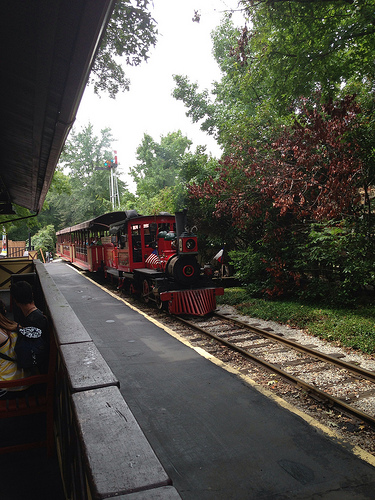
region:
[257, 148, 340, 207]
brown leaves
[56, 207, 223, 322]
a red and black train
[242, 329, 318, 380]
railroad tracks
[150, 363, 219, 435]
black pavement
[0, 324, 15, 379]
a yellow and white shirt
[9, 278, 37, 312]
a person with black hair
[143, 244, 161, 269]
a red, white and blue flag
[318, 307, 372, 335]
green grass with brown leaves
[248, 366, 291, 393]
green and brown leaves on a railroad track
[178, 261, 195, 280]
a red circle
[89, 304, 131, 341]
small spot on platform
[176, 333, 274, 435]
yellow line on side of platform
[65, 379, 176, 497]
large gray stones on side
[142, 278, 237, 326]
front of red train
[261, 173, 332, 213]
red leaves on trees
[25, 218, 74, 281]
large green tree in the background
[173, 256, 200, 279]
large red circle on front of train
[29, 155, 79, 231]
overhead hang on platform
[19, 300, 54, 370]
person standing on side of platform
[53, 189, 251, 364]
large red train on track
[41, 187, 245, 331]
an old timey train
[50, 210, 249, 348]
the train is red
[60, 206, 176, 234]
the train has a black roof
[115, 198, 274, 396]
the train is on a track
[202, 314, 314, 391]
the track has gravel in the middle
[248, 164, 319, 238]
the tree is red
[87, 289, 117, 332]
the sidewalk is black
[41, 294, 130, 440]
concrete blocks line the sidewalk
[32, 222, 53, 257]
green trees are in the background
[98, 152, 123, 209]
a signal light is in the background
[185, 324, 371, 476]
the train track is metal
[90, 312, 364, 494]
the walkway by train is asphault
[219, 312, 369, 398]
gravel lays between tracks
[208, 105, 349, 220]
this tree has red leaves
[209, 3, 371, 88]
the trees have green leaves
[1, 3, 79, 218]
the station has a roof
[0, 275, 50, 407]
people are waiting for the train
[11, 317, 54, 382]
she has a backpack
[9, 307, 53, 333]
his shirt is black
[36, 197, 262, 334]
A red train on tracks.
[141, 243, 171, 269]
American flag on the train.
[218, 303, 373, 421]
The tracks are brown.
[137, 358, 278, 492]
The platform is black.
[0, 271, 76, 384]
People sitting on a bench.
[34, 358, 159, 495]
A wall made of stone.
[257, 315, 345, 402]
Gravel around the tracks.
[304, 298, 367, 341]
The grass is green.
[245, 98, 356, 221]
The leaves are red.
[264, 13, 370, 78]
The leaves are green.